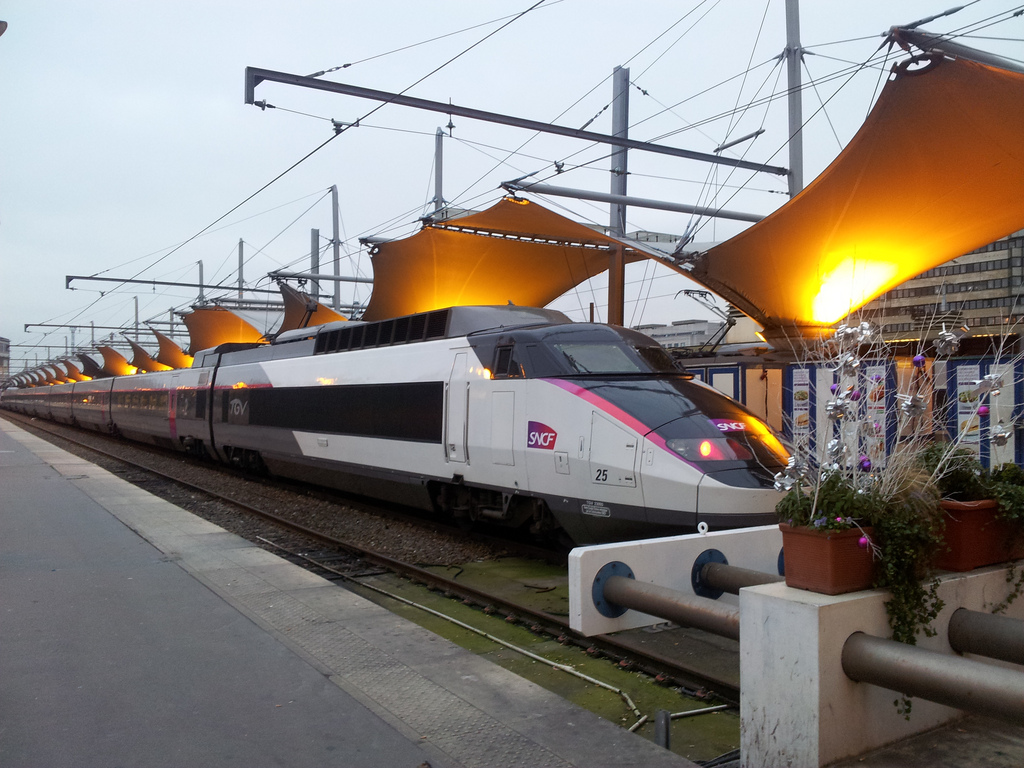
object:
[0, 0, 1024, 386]
clouds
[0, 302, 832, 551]
car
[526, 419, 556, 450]
sign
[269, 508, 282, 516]
rock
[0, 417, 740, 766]
street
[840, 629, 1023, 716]
pipes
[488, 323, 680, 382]
window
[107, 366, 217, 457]
passenger car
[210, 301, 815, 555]
engine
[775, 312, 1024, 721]
plants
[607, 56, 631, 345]
pole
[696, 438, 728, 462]
light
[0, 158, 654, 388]
canopy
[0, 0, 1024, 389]
wire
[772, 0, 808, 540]
pole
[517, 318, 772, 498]
trim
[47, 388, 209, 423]
windows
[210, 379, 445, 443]
side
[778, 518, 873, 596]
box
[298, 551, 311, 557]
gravel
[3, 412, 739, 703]
tracks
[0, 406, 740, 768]
platform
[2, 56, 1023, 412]
canopy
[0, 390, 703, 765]
train platform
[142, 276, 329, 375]
canopy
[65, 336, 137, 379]
canopy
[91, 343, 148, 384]
canopy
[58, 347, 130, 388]
canopy